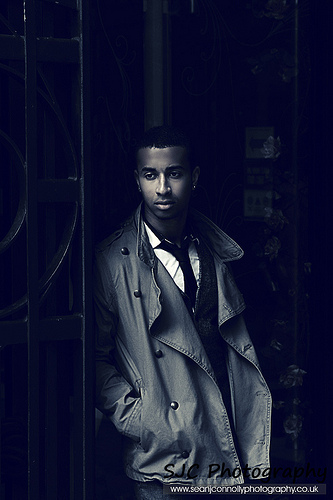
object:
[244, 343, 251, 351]
hole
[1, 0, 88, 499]
gate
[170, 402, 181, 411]
button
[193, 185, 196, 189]
earring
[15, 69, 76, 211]
iron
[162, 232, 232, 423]
vest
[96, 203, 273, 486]
coat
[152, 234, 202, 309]
tie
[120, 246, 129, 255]
button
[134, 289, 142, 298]
button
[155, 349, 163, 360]
button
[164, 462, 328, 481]
photographer logo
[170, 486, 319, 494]
photographer name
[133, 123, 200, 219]
head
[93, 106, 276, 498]
male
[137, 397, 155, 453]
pocket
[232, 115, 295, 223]
sign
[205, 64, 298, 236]
glass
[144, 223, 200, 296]
shirt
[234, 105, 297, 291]
reflections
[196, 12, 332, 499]
glass door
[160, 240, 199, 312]
necktie